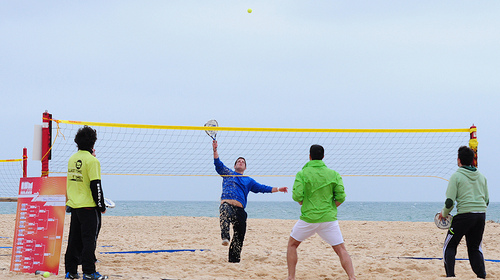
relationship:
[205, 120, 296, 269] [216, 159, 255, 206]
man wearing shirt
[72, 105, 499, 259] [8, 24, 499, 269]
people are playing tennis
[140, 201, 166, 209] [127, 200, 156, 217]
body of water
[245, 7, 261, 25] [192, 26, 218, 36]
ball in air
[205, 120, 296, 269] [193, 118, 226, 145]
man holding racket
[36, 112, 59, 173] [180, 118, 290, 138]
pole for net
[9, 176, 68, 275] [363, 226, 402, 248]
sign in sand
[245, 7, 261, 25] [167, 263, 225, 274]
ball on ground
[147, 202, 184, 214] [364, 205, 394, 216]
ocean has waves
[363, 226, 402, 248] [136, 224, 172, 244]
sand on beach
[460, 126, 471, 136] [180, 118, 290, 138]
edge of net